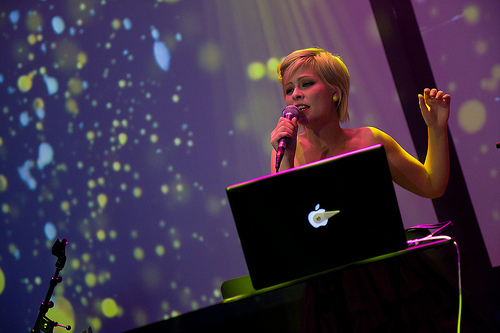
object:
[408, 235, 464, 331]
wire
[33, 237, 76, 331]
instrument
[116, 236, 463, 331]
black podium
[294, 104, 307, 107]
teeth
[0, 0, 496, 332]
stage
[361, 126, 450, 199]
arm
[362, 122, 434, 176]
light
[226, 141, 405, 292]
black laptop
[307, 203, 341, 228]
apple logo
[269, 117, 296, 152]
hand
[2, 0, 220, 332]
wall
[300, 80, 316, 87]
eye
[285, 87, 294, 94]
eye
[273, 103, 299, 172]
mic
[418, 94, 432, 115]
fingers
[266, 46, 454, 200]
girl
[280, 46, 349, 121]
hair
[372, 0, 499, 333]
pillar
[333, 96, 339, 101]
earing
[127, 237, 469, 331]
table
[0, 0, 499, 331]
designs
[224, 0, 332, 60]
light rays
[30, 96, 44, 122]
dots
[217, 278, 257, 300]
chair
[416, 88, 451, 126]
hand